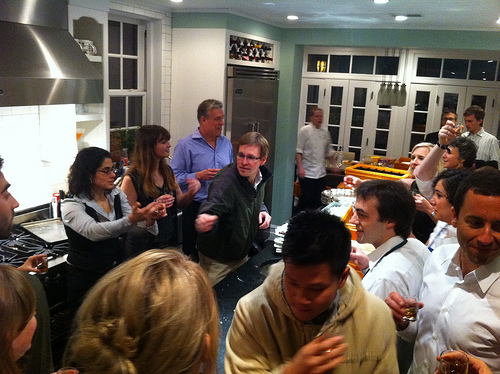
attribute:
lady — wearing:
[59, 143, 175, 311]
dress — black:
[62, 183, 139, 318]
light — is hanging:
[280, 8, 312, 38]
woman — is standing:
[53, 141, 156, 253]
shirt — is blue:
[171, 124, 265, 189]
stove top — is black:
[0, 210, 68, 267]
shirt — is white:
[411, 240, 499, 368]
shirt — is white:
[362, 233, 433, 330]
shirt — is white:
[461, 129, 498, 162]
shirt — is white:
[403, 247, 497, 331]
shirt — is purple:
[156, 89, 233, 190]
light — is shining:
[9, 93, 91, 154]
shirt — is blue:
[172, 126, 237, 203]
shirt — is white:
[359, 239, 443, 300]